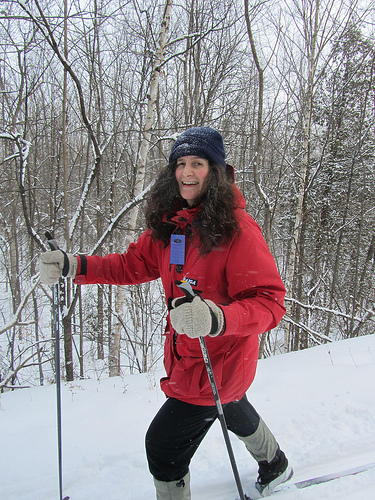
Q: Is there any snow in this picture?
A: Yes, there is snow.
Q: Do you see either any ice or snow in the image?
A: Yes, there is snow.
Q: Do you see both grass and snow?
A: No, there is snow but no grass.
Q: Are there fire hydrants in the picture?
A: No, there are no fire hydrants.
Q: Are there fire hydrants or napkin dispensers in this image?
A: No, there are no fire hydrants or napkin dispensers.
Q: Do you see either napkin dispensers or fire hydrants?
A: No, there are no fire hydrants or napkin dispensers.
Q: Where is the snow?
A: The snow is on the ground.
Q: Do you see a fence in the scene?
A: No, there are no fences.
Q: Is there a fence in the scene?
A: No, there are no fences.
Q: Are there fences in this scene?
A: No, there are no fences.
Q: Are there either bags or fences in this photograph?
A: No, there are no fences or bags.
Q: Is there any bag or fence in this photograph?
A: No, there are no fences or bags.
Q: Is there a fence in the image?
A: No, there are no fences.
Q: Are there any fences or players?
A: No, there are no fences or players.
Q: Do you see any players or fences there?
A: No, there are no fences or players.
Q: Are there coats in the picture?
A: Yes, there is a coat.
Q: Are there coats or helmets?
A: Yes, there is a coat.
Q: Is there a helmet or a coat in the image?
A: Yes, there is a coat.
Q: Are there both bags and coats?
A: No, there is a coat but no bags.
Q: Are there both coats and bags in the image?
A: No, there is a coat but no bags.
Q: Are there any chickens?
A: No, there are no chickens.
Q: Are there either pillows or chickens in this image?
A: No, there are no chickens or pillows.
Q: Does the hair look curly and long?
A: Yes, the hair is curly and long.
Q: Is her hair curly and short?
A: No, the hair is curly but long.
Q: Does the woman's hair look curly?
A: Yes, the hair is curly.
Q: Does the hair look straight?
A: No, the hair is curly.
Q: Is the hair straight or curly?
A: The hair is curly.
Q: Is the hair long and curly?
A: Yes, the hair is long and curly.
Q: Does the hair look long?
A: Yes, the hair is long.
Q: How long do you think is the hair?
A: The hair is long.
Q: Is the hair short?
A: No, the hair is long.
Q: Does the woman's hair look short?
A: No, the hair is long.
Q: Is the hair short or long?
A: The hair is long.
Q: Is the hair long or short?
A: The hair is long.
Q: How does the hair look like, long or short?
A: The hair is long.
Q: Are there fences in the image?
A: No, there are no fences.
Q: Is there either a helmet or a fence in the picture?
A: No, there are no fences or helmets.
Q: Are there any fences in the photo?
A: No, there are no fences.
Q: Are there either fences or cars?
A: No, there are no fences or cars.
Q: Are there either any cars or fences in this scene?
A: No, there are no fences or cars.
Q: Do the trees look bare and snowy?
A: Yes, the trees are bare and snowy.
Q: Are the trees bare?
A: Yes, the trees are bare.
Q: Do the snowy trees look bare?
A: Yes, the trees are bare.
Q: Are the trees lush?
A: No, the trees are bare.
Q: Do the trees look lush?
A: No, the trees are bare.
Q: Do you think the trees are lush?
A: No, the trees are bare.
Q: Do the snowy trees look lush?
A: No, the trees are bare.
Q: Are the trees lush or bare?
A: The trees are bare.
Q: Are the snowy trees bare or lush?
A: The trees are bare.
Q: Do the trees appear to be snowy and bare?
A: Yes, the trees are snowy and bare.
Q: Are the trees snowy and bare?
A: Yes, the trees are snowy and bare.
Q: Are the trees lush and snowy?
A: No, the trees are snowy but bare.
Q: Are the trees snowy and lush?
A: No, the trees are snowy but bare.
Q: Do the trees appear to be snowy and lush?
A: No, the trees are snowy but bare.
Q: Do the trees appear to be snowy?
A: Yes, the trees are snowy.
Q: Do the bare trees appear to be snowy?
A: Yes, the trees are snowy.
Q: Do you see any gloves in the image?
A: Yes, there are gloves.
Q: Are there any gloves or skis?
A: Yes, there are gloves.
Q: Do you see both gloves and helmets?
A: No, there are gloves but no helmets.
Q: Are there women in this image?
A: Yes, there is a woman.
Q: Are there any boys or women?
A: Yes, there is a woman.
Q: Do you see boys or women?
A: Yes, there is a woman.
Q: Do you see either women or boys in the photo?
A: Yes, there is a woman.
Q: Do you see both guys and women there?
A: No, there is a woman but no guys.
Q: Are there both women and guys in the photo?
A: No, there is a woman but no guys.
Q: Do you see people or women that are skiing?
A: Yes, the woman is skiing.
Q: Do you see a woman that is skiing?
A: Yes, there is a woman that is skiing.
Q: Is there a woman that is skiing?
A: Yes, there is a woman that is skiing.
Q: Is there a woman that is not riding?
A: Yes, there is a woman that is skiing.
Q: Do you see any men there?
A: No, there are no men.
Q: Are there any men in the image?
A: No, there are no men.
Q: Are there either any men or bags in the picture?
A: No, there are no men or bags.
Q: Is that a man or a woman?
A: That is a woman.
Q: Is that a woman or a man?
A: That is a woman.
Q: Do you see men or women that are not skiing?
A: No, there is a woman but she is skiing.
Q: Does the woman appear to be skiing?
A: Yes, the woman is skiing.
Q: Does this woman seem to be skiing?
A: Yes, the woman is skiing.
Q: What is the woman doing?
A: The woman is skiing.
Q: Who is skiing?
A: The woman is skiing.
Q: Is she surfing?
A: No, the woman is skiing.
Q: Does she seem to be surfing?
A: No, the woman is skiing.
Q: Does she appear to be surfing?
A: No, the woman is skiing.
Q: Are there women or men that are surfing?
A: No, there is a woman but she is skiing.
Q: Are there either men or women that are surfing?
A: No, there is a woman but she is skiing.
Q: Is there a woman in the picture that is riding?
A: No, there is a woman but she is skiing.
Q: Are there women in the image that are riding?
A: No, there is a woman but she is skiing.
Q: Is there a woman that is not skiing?
A: No, there is a woman but she is skiing.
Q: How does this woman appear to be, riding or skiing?
A: The woman is skiing.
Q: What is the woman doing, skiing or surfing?
A: The woman is skiing.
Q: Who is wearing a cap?
A: The woman is wearing a cap.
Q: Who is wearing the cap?
A: The woman is wearing a cap.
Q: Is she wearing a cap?
A: Yes, the woman is wearing a cap.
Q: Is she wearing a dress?
A: No, the woman is wearing a cap.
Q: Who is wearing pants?
A: The woman is wearing pants.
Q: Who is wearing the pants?
A: The woman is wearing pants.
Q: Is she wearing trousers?
A: Yes, the woman is wearing trousers.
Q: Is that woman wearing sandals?
A: No, the woman is wearing trousers.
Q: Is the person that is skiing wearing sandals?
A: No, the woman is wearing trousers.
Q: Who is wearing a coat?
A: The woman is wearing a coat.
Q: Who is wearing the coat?
A: The woman is wearing a coat.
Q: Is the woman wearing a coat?
A: Yes, the woman is wearing a coat.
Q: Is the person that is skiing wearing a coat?
A: Yes, the woman is wearing a coat.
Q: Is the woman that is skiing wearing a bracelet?
A: No, the woman is wearing a coat.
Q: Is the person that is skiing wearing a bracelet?
A: No, the woman is wearing a coat.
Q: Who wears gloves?
A: The woman wears gloves.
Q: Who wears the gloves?
A: The woman wears gloves.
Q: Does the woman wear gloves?
A: Yes, the woman wears gloves.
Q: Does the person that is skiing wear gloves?
A: Yes, the woman wears gloves.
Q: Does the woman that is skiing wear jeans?
A: No, the woman wears gloves.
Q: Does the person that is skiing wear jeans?
A: No, the woman wears gloves.